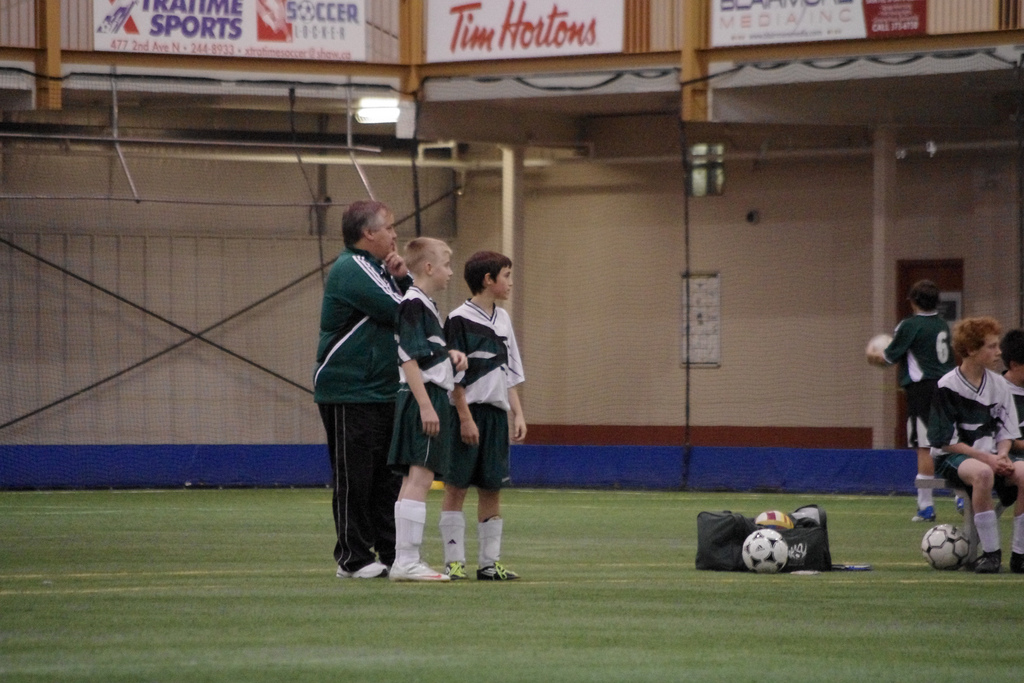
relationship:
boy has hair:
[378, 230, 471, 583] [391, 232, 450, 272]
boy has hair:
[436, 236, 534, 586] [464, 246, 516, 298]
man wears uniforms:
[309, 199, 416, 579] [315, 293, 527, 538]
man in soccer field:
[309, 199, 416, 579] [6, 490, 1011, 679]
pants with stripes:
[309, 394, 403, 576] [324, 402, 351, 560]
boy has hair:
[378, 230, 471, 583] [398, 232, 453, 267]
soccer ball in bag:
[734, 523, 795, 578] [689, 504, 839, 572]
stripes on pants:
[326, 398, 357, 567] [317, 398, 400, 569]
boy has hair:
[436, 236, 534, 586] [456, 249, 502, 286]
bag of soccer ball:
[689, 504, 839, 572] [739, 521, 794, 573]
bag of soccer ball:
[689, 504, 839, 572] [752, 508, 798, 528]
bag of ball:
[689, 504, 839, 572] [742, 529, 790, 573]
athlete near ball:
[863, 276, 959, 523] [920, 523, 973, 570]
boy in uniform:
[378, 230, 471, 583] [385, 282, 455, 490]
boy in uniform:
[436, 236, 534, 586] [438, 292, 529, 496]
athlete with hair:
[906, 309, 1023, 536] [930, 309, 1011, 405]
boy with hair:
[437, 249, 529, 579] [468, 242, 518, 305]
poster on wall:
[675, 268, 740, 385] [96, 104, 913, 534]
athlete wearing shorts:
[923, 316, 1024, 570] [920, 433, 985, 511]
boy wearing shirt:
[388, 236, 470, 584] [296, 256, 428, 393]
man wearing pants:
[274, 161, 581, 604] [304, 379, 426, 596]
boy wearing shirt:
[388, 236, 470, 584] [335, 249, 511, 390]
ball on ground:
[741, 530, 821, 583] [505, 592, 720, 659]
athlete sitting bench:
[818, 323, 989, 605] [875, 458, 992, 554]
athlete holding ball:
[923, 316, 1024, 570] [920, 491, 990, 571]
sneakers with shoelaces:
[415, 551, 521, 575] [466, 545, 551, 576]